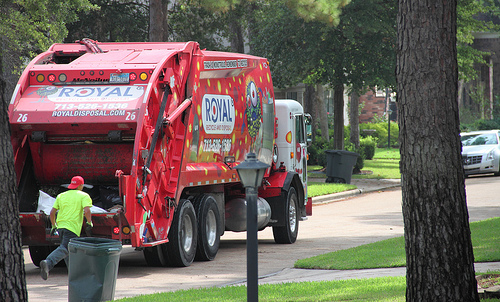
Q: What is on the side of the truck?
A: Royal.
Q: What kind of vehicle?
A: Truck.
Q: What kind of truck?
A: Trash truck.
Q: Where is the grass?
A: In yards.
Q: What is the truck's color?
A: Red.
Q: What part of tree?
A: Trunk.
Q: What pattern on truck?
A: Polka dots.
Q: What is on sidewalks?
A: Grass.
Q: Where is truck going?
A: Down the street.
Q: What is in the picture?
A: A garbage truck.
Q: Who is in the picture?
A: A man.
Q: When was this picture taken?
A: Daytime.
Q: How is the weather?
A: Clear.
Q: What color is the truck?
A: Red.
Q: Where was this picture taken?
A: A street.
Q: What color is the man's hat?
A: Red.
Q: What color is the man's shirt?
A: Green.